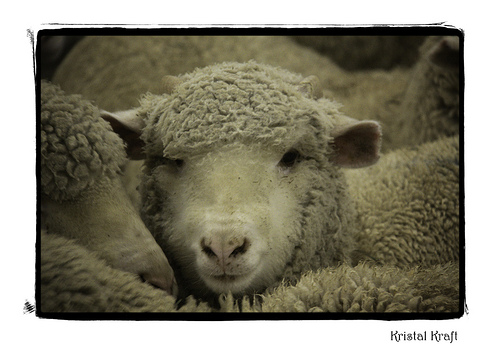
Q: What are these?
A: Sheep.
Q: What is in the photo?
A: Animals.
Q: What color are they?
A: White.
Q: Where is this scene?
A: On a farm.